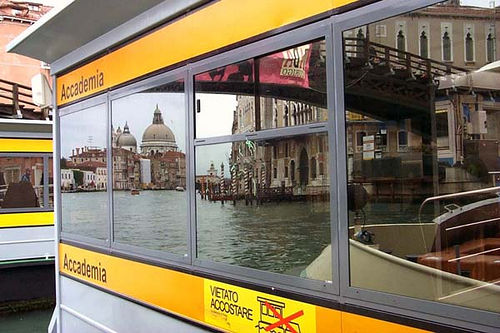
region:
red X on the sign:
[260, 296, 309, 331]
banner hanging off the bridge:
[203, 43, 318, 83]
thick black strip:
[3, 138, 55, 152]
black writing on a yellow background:
[53, 66, 113, 107]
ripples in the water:
[216, 216, 280, 257]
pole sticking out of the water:
[228, 165, 240, 205]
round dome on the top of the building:
[138, 103, 180, 148]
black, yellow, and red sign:
[195, 281, 320, 331]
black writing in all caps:
[207, 284, 254, 319]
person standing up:
[18, 166, 35, 182]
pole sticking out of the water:
[217, 164, 231, 202]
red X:
[261, 299, 311, 331]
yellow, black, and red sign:
[199, 274, 321, 331]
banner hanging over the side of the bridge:
[206, 38, 316, 86]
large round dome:
[136, 103, 181, 146]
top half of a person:
[18, 166, 31, 179]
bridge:
[293, 39, 472, 116]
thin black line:
[61, 238, 142, 266]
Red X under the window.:
[261, 297, 308, 332]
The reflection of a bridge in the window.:
[128, 31, 478, 137]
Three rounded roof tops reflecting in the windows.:
[107, 121, 136, 148]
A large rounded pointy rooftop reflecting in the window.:
[140, 102, 177, 151]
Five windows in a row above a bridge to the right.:
[393, 29, 495, 64]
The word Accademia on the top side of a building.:
[51, 66, 104, 97]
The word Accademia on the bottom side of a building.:
[60, 251, 107, 282]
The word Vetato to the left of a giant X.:
[207, 284, 242, 302]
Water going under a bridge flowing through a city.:
[63, 189, 450, 282]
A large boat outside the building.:
[292, 173, 497, 313]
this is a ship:
[111, 47, 465, 312]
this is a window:
[191, 67, 326, 252]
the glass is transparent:
[246, 172, 280, 249]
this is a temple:
[141, 106, 178, 169]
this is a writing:
[57, 250, 102, 280]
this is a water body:
[216, 195, 287, 255]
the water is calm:
[231, 210, 291, 260]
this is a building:
[435, 10, 487, 51]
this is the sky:
[122, 100, 142, 117]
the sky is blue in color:
[67, 116, 98, 126]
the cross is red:
[279, 306, 285, 328]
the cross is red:
[269, 305, 284, 325]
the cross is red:
[273, 304, 293, 329]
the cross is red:
[274, 324, 280, 331]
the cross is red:
[270, 310, 282, 330]